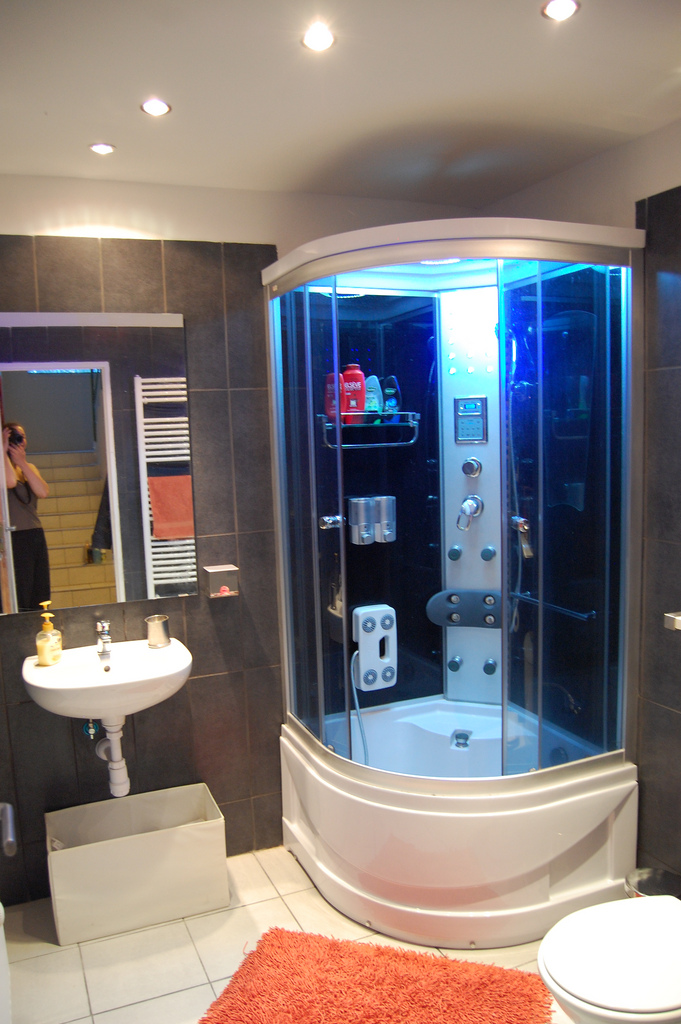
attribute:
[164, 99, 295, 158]
ceiling — white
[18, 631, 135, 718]
sink — white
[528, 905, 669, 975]
toilet — white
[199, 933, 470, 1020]
mat — orange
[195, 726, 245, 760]
wall — black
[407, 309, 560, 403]
light — on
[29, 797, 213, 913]
tub — large, whtie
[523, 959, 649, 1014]
toilet bowl — white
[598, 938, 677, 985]
lid — white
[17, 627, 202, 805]
sink — white, bathroom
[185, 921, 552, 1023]
rug — pink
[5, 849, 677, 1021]
floor — bathroom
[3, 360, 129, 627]
mirror — large, rectangular, shiny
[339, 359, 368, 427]
bottle — shower gel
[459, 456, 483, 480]
knob — water control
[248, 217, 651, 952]
shower — hi-tech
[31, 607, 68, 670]
bottle — large, soap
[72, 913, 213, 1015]
tile — square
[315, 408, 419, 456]
shelf — silver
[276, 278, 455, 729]
wall — shower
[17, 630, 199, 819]
sink — white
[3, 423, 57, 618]
reflection — person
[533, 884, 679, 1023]
toilet — white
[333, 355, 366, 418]
bottles — red, shampoo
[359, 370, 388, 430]
bottles — shampoo, white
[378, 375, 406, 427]
bottle — black, white, shampoo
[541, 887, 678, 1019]
top — white, toilet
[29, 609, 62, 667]
bottle — pump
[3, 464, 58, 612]
dress — black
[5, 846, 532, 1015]
floor — white, tiles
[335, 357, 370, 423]
bottle — red